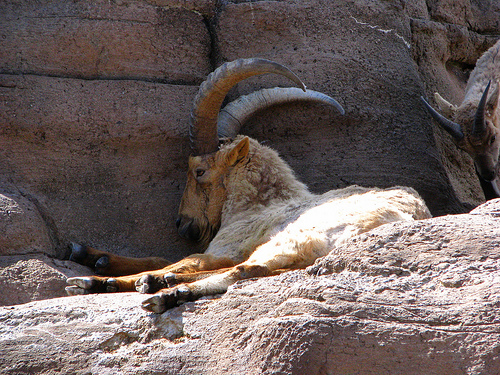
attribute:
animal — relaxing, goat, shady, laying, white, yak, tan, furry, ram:
[64, 58, 431, 311]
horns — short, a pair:
[190, 57, 343, 155]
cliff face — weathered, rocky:
[0, 197, 499, 374]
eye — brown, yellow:
[192, 167, 206, 178]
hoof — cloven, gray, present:
[64, 276, 117, 296]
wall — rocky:
[0, 0, 490, 263]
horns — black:
[418, 78, 491, 141]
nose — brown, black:
[175, 212, 186, 236]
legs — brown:
[69, 242, 299, 314]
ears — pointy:
[232, 135, 250, 162]